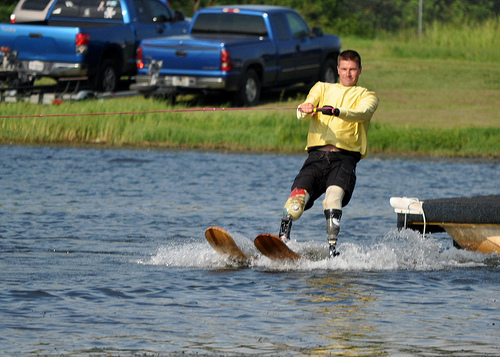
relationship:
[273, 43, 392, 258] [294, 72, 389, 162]
guy wearing shirt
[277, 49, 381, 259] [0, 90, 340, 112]
guy holding on to rope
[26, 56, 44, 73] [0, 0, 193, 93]
license plate on blue truck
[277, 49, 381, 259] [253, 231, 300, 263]
guy riding ski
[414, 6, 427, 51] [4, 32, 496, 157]
pole in field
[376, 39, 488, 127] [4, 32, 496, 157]
grass in field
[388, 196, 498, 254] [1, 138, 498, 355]
dock in water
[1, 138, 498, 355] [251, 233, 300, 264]
water splashing from ski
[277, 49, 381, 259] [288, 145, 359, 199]
guy wearing shorts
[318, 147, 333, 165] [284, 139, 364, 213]
drawstring on shorts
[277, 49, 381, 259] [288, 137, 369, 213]
guy wearing shorts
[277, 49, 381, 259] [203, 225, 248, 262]
guy on ski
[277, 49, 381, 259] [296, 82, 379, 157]
guy wearing top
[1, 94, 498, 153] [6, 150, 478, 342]
grass along water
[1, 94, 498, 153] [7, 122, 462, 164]
grass along bank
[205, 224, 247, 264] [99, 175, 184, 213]
ski on water